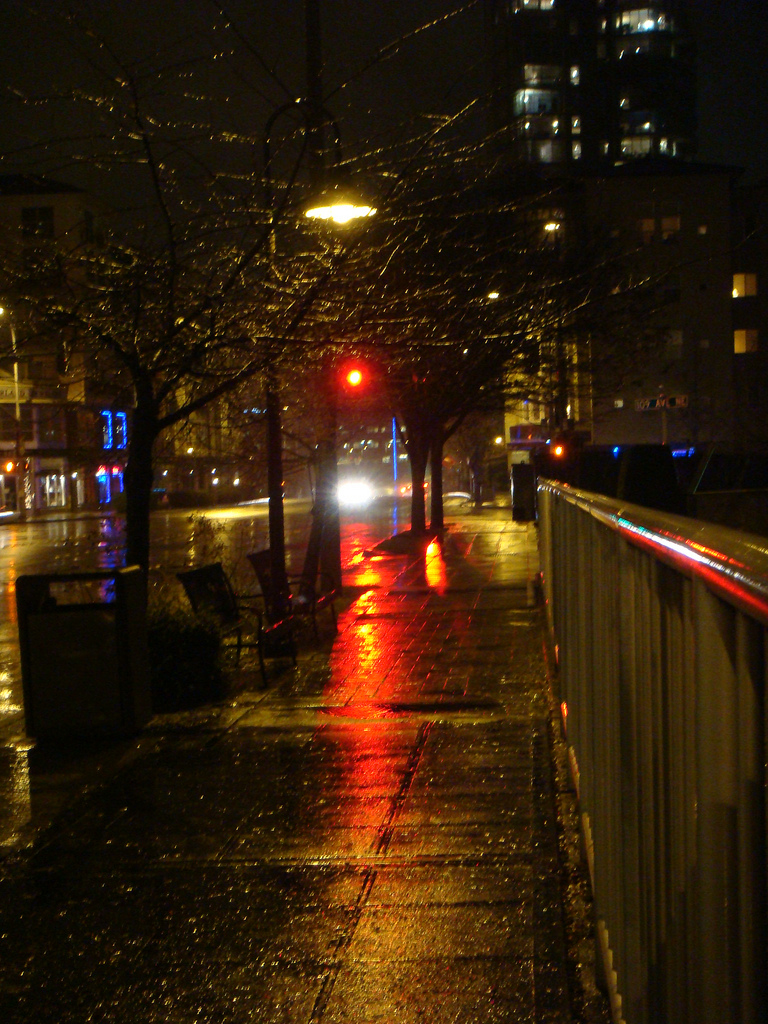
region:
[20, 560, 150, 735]
A black trash can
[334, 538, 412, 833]
Light reflecting on the sidewalk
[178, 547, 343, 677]
Black benches on the sidewalk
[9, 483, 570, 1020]
A wet sidewalk by the road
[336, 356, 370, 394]
A red stoplight over the road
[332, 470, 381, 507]
The bright white light of a car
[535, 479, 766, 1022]
A metal fence by the sidewalk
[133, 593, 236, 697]
A small bush by the trash can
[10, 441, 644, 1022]
the ground is wet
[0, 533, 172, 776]
trash can on the side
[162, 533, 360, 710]
a set of benches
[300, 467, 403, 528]
lights in the distance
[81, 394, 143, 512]
lights on the building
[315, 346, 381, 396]
a red traffic light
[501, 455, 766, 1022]
railing on the side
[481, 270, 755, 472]
building on the side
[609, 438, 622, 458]
Blue light on the side of the pole.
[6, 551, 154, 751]
Trash can on top of the sidewalk.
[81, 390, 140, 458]
Blue lit up signs on the side of the building.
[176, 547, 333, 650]
Two benches on the sidewalk.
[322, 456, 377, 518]
Car light lit up in the dark.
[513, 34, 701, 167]
Bunch of lights on the side of the building.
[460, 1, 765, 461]
Large apartment building on the corner.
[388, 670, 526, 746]
Hole in the sidewalk by the rail.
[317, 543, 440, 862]
reflection of lights on sidewalk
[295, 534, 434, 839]
stop light reflecting on wet sidewalk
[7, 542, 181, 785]
trash can near street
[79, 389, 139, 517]
neon lights in business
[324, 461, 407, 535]
headlights on car approaching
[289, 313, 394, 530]
car stopped at red light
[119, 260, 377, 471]
trees that have been rained on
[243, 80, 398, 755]
streetlight on sidewalk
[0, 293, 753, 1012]
A city at night.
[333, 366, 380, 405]
A traffic light.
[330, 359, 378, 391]
A red light.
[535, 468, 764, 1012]
A grey metal fence.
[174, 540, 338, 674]
Empty benches.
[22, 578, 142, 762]
A trash bin.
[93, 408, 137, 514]
Blue neon lights in the window front.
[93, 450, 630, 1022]
The sidewalk.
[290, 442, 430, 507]
An oncoming vehicle.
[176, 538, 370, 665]
bench on a side walk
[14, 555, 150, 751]
garbage can near side walk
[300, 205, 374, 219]
a light is on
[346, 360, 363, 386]
a light is on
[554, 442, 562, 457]
a light is on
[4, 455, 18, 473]
the light is red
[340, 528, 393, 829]
the reflection is red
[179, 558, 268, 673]
bench on side walk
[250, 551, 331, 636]
the bench is dark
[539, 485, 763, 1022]
the fence is wood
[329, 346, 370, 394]
red light of the traffic signal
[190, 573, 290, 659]
wooden bench on the street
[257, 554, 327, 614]
right side wooden bench on the street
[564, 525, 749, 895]
metal fence on the street in the right side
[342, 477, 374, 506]
shine of the hight light of the car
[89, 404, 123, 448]
neon light outside a shop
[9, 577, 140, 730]
trash pack box on the street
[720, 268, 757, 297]
turning on light on the window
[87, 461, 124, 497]
below neon light outside a shop